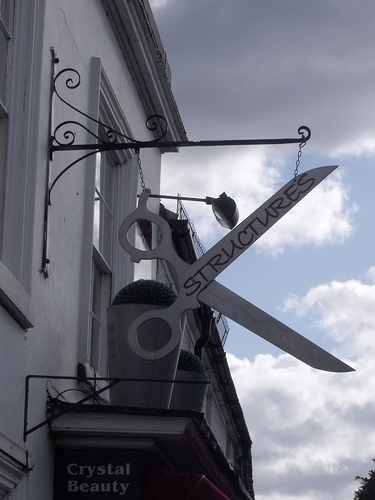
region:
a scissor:
[69, 114, 361, 412]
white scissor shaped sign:
[71, 154, 334, 368]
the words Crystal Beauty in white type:
[57, 452, 138, 497]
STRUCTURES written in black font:
[169, 147, 335, 324]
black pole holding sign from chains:
[41, 58, 316, 180]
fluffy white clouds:
[244, 335, 374, 476]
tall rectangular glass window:
[84, 93, 133, 399]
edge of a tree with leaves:
[350, 452, 374, 499]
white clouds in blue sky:
[173, 90, 355, 235]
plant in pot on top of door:
[109, 273, 192, 414]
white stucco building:
[0, 5, 258, 455]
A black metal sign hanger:
[47, 44, 321, 316]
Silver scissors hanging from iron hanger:
[123, 170, 361, 388]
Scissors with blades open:
[106, 164, 362, 402]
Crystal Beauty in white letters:
[60, 455, 137, 498]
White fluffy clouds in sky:
[184, 160, 369, 499]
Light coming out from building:
[137, 181, 258, 253]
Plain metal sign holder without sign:
[16, 356, 216, 473]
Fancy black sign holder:
[50, 49, 324, 278]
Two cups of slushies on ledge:
[94, 270, 208, 438]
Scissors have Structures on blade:
[105, 146, 353, 382]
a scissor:
[135, 155, 329, 378]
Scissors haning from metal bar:
[104, 156, 360, 386]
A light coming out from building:
[134, 179, 245, 245]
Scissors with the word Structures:
[119, 166, 354, 391]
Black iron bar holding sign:
[47, 47, 322, 271]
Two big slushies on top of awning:
[98, 272, 224, 430]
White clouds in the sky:
[181, 148, 365, 493]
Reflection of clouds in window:
[94, 143, 106, 249]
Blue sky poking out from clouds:
[158, 132, 374, 360]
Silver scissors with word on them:
[112, 161, 365, 394]